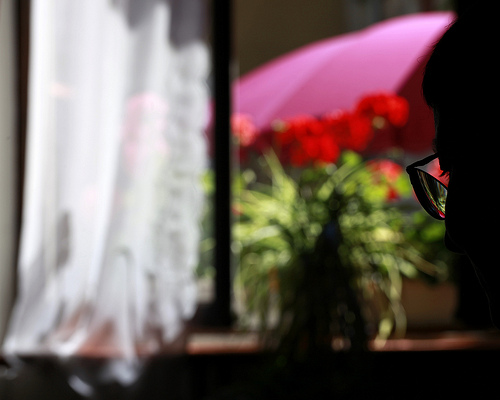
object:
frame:
[193, 0, 244, 329]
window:
[11, 2, 235, 328]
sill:
[176, 335, 493, 354]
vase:
[268, 262, 364, 356]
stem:
[230, 147, 435, 349]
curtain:
[5, 0, 208, 392]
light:
[187, 331, 266, 345]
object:
[290, 194, 366, 367]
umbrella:
[237, 11, 460, 156]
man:
[406, 5, 499, 331]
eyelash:
[439, 170, 446, 177]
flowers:
[233, 89, 451, 363]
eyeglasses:
[406, 153, 448, 220]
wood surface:
[189, 338, 471, 357]